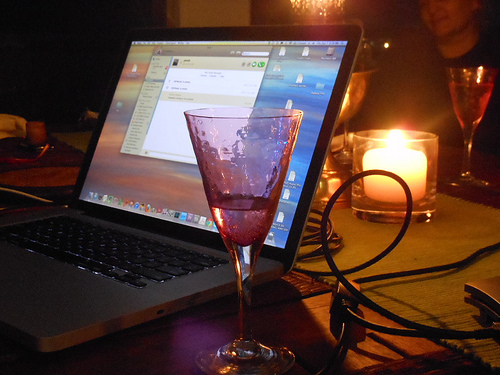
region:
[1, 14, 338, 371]
silver laptop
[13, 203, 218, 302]
black keys on the silver keyboard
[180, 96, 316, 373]
glass sitting next to the laptop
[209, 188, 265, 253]
small amount of liquid in the glass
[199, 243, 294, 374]
stem of the glass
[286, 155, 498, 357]
black cord that is curled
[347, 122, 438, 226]
lit candle on the table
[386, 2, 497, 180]
person sitting at the table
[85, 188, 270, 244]
row of small icons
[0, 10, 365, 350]
laptop is on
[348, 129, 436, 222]
a votive candle in a glass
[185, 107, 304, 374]
a pink glass on a table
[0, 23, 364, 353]
a laptop on a table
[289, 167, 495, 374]
a bunch of black wires on a table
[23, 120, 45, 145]
a candle on a table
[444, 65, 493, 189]
a full glass of wine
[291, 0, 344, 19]
the tip of a chandelier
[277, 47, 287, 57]
a white icon on a laptop screen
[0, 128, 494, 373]
a red tablecloth on a wooden table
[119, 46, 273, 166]
a window on a laptop screen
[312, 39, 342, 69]
Small icon on a computer screen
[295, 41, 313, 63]
Small icon on a computer screen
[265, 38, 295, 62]
Small icon on a computer screen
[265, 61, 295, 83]
Small icon on a computer screen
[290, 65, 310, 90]
Small icon on a computer screen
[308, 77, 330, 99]
Small icon on a computer screen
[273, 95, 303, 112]
Small icon on a computer screen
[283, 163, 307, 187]
Small icon on a computer screen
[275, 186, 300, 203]
Small icon on a computer screen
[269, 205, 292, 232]
Small icon on a computer screen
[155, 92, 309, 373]
this is a glass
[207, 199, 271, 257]
a liquid ina glass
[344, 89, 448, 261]
this is a candle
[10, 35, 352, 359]
this is a laptop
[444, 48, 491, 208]
this is a glass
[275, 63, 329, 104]
this is an icon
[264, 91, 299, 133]
this is an icon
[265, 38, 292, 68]
this is an icon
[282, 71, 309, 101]
this is an icon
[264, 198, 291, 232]
this is an icon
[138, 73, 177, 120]
the laptop is on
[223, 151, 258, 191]
the cup is purple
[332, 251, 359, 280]
the cord is black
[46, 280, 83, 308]
the laptop is gray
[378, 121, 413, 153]
the candle is lite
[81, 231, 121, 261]
the keyboard is black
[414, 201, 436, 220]
the glass is clear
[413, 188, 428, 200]
the candle is white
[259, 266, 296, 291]
the laptop is on the mat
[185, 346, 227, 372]
the glass is on the table